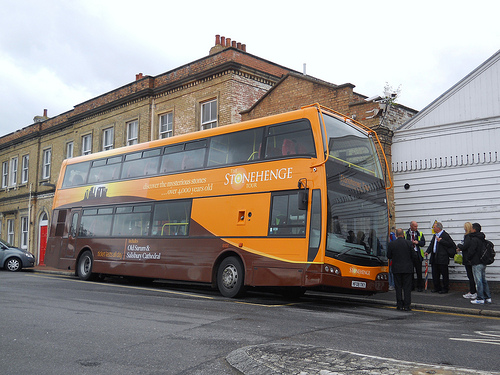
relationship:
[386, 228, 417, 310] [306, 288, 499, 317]
people on sidewalk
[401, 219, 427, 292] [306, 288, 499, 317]
people on sidewalk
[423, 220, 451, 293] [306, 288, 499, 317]
man on sidewalk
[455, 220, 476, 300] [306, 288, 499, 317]
people on sidewalk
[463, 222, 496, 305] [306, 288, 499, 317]
man on sidewalk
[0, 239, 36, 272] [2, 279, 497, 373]
car on street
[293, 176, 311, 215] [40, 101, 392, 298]
mirror on bus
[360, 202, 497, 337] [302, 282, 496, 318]
people standing on sidewalk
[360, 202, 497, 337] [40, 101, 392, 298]
people outside of bus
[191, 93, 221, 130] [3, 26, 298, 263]
white windows in brick building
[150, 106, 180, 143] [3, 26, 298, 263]
white windows in brick building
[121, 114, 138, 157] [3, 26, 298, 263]
white windows in brick building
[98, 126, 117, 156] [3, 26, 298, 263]
white windows in brick building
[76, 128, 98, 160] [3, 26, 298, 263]
white windows in brick building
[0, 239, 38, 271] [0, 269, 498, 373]
car parked on street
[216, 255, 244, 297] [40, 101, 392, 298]
front wheel on bus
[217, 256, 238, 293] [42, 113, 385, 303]
front wheel of bus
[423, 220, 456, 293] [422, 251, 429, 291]
man holding umbrella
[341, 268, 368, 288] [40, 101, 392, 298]
number plate on bus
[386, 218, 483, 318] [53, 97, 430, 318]
people standing near bus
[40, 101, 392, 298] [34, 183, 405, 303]
bus has lower level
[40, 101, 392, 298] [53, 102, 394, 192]
bus has top level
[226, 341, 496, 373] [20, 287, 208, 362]
island in street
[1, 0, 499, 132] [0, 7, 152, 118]
sky has clouds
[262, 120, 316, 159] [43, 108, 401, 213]
window on top level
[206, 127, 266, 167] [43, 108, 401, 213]
window on top level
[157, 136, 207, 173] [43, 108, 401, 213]
window on top level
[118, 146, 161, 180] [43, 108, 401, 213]
window on top level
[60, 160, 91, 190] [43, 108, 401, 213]
window on top level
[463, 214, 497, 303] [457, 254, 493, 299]
man wearing jeans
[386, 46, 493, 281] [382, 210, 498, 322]
building behind people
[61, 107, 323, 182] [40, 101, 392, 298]
part on bus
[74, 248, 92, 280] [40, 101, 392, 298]
tire on bus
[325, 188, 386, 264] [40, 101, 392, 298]
front glass on bus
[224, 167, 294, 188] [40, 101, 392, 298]
letters on bus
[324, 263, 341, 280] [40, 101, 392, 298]
light on bus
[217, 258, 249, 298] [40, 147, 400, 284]
wheel on bus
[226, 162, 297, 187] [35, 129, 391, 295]
letters on bus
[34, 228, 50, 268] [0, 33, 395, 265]
red door of brick building